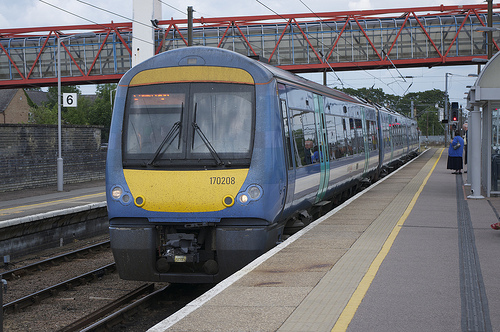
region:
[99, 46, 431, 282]
a train in a train station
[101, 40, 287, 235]
the front of the train is blue and yellow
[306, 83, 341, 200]
the train has double doors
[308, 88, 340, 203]
the doors of the train are green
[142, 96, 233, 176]
two wipes on windshield of train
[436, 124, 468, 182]
woman stand on a train station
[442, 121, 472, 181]
woman wears blue shirt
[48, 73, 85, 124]
number 6 in a pole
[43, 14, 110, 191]
lights on a train station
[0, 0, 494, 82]
a bridge over a train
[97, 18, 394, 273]
the train at the train station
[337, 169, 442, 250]
the line is yellow and white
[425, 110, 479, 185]
people at the platform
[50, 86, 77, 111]
the number is 6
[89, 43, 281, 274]
the train is blue and yellow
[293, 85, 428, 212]
the doors are closed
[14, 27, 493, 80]
the bars are red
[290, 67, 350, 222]
the door is green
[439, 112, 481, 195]
the people are standing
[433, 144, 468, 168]
a woman wearing a skirt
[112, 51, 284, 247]
front of blue bus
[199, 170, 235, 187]
number on front of bus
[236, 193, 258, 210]
small round headlight on train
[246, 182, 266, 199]
larger round headlight on train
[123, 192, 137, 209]
small round headlight on train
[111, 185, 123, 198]
larger headlight and train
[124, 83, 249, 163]
front windshield on train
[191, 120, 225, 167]
windshield wiper on train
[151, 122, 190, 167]
windshield wiper on train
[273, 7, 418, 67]
walkway above train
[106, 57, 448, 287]
light blue and yellow train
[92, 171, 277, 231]
two front lights of a light blue and yellow train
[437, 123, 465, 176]
a woman with blue t-shirt on train station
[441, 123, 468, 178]
a fat woman in train stration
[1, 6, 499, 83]
red gangway upon yellow and light blue train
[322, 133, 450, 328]
yellow line in the floor of the right side train station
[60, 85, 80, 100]
6 sign number in the left side of train station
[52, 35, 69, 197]
grey pole with 6 numer sign on it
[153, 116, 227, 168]
two windshield wiper in front of the yellow and light blue train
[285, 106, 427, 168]
black windows of a light blue and yellow train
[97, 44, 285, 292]
front of train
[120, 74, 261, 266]
windshield on blue and yellow train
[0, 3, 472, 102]
walkway located above train tracks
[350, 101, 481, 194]
woman standing waiting for train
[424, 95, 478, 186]
woman standing below red stoplight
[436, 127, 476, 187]
woman dressed in black skirt and blue shirt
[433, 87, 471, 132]
stoplight with red light shining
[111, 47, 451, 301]
train number 170208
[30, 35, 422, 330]
train at station number 6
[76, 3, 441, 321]
train located under walkway